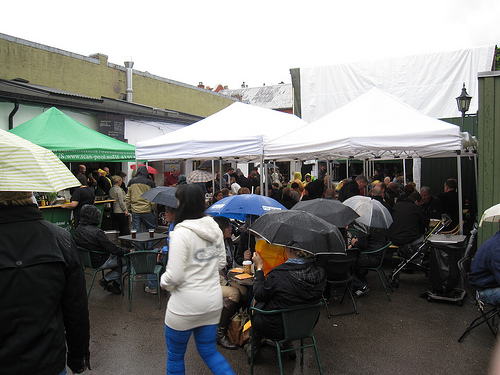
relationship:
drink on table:
[117, 204, 160, 240] [125, 236, 164, 298]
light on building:
[436, 77, 479, 121] [1, 55, 233, 125]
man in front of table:
[74, 186, 131, 292] [125, 236, 164, 298]